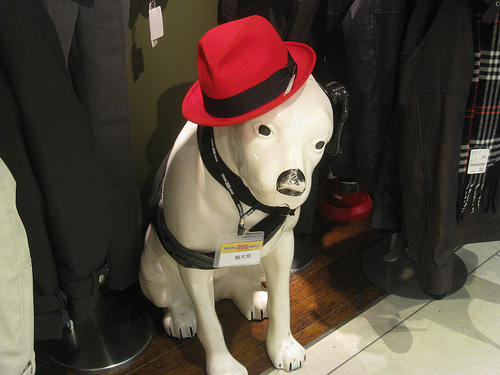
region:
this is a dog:
[158, 29, 320, 366]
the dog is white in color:
[278, 110, 303, 152]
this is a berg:
[216, 224, 266, 268]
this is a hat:
[206, 30, 291, 103]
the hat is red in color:
[227, 48, 259, 78]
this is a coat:
[372, 20, 454, 266]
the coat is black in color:
[34, 106, 67, 191]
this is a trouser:
[85, 26, 115, 100]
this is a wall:
[157, 55, 172, 128]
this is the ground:
[309, 291, 408, 373]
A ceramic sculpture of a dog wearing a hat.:
[135, 11, 338, 373]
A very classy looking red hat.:
[179, 12, 317, 129]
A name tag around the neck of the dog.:
[210, 230, 266, 268]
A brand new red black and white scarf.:
[457, 0, 498, 218]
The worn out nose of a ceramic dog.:
[274, 167, 307, 195]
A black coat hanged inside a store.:
[0, 1, 116, 346]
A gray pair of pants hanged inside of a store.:
[42, 0, 144, 291]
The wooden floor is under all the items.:
[35, 207, 407, 374]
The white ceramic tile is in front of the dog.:
[265, 242, 497, 373]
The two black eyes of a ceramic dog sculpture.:
[255, 123, 327, 151]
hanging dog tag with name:
[201, 221, 292, 273]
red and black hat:
[172, 23, 321, 132]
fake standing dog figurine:
[157, 36, 345, 366]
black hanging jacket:
[330, 8, 496, 300]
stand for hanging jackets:
[38, 286, 163, 371]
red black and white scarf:
[470, 5, 499, 232]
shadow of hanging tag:
[127, 6, 172, 81]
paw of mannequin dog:
[257, 322, 310, 372]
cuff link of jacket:
[62, 265, 120, 295]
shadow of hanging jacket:
[328, 230, 496, 360]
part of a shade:
[376, 324, 408, 359]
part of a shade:
[355, 287, 414, 326]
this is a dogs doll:
[143, 46, 350, 336]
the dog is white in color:
[159, 110, 336, 307]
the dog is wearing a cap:
[206, 27, 288, 116]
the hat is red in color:
[235, 36, 285, 91]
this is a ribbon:
[230, 197, 258, 224]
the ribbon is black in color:
[221, 176, 237, 188]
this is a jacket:
[414, 64, 461, 156]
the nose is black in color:
[275, 170, 305, 197]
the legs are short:
[226, 270, 297, 363]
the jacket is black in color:
[416, 81, 459, 181]